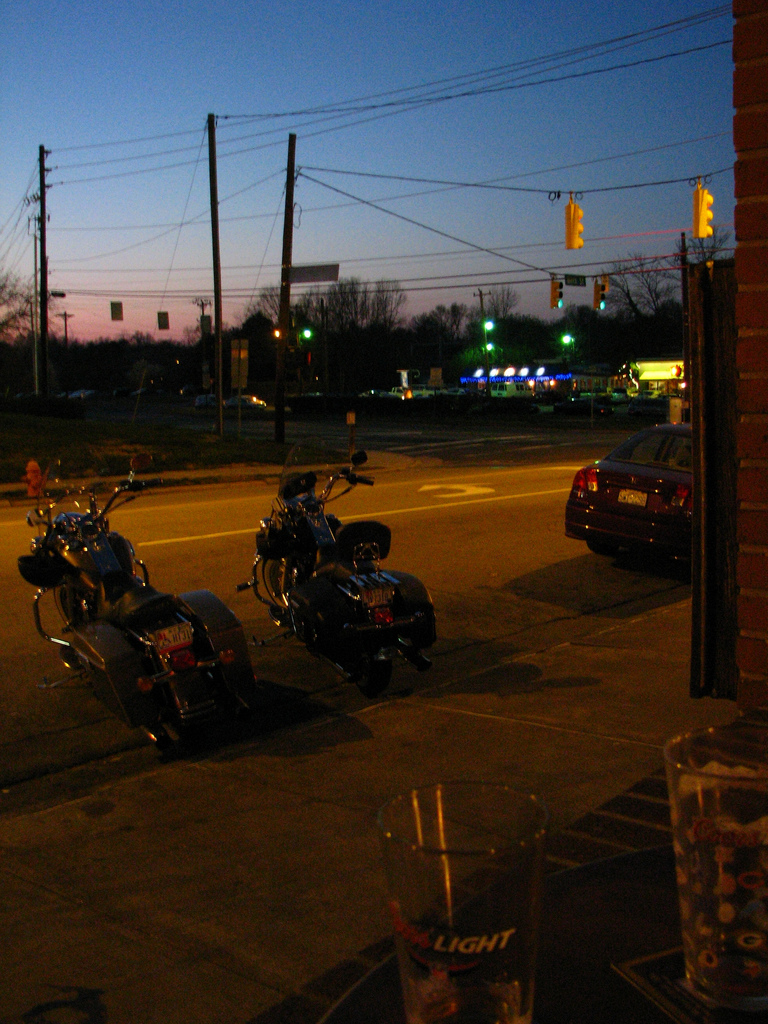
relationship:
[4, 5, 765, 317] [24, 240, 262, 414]
wires from poles